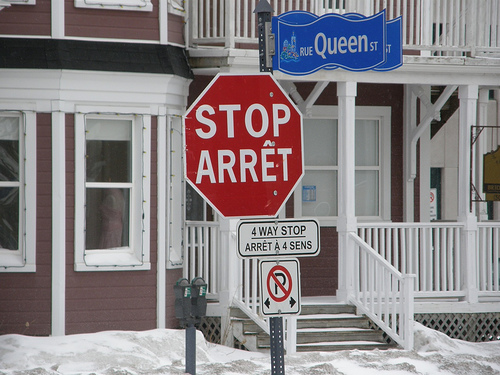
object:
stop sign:
[184, 71, 303, 224]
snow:
[0, 302, 500, 375]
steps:
[228, 309, 402, 353]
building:
[0, 0, 500, 348]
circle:
[266, 266, 289, 304]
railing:
[247, 220, 500, 349]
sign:
[426, 184, 444, 219]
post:
[331, 83, 357, 298]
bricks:
[167, 33, 187, 45]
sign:
[276, 2, 404, 78]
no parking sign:
[254, 261, 304, 319]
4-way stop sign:
[238, 220, 335, 257]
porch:
[355, 74, 500, 297]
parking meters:
[180, 271, 221, 318]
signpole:
[254, 1, 274, 72]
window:
[76, 113, 152, 272]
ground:
[0, 327, 500, 373]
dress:
[98, 183, 128, 249]